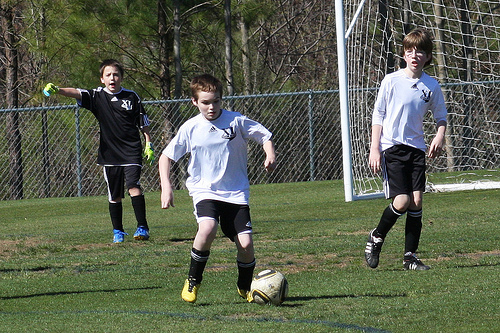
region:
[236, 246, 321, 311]
The soccer ball is on the ground.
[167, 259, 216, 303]
The boy is wearing yellow sneakers.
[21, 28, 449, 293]
The kids are playing soccer.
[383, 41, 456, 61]
the boy is wearing glasses.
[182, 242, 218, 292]
The boy has on black socks.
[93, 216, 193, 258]
The boy is wearing blue tennis shoes.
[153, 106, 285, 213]
The boy has on a white tee shirt.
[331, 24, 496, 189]
The white net is behind the boy.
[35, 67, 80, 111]
The boy is wearing gloves.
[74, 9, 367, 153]
Trees behind the fenced gate.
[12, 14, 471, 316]
Three young boys playing soccer.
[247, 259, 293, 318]
A white soccer ball.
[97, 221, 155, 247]
A pair of blue tennis shoes.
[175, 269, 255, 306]
A pair of yellow tennis shoes.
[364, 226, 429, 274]
A pair of black tennis shoes.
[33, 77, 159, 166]
Boy wearing yellow gloves.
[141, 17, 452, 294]
Two boys wearing same uniform.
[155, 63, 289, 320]
Boy getting ready to kick soccer ball.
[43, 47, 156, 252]
Boy wearing black uniform.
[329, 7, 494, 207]
Part of the white soccer goal.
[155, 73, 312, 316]
boy near soccer ball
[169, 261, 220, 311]
yellow shoe with black lace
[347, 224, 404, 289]
black and white shoe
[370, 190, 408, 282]
black sock with white trim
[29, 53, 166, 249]
boy yelling and pointing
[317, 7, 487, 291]
soccer goal behind player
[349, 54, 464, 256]
white shirt and black shorts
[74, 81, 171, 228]
black shirt and shorts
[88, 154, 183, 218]
white stripe on black shorts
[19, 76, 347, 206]
chain link fence behind soccer players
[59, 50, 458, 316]
Three boys playing soccer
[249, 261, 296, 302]
White soccer ball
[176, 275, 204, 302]
Cleat is yellow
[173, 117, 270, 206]
Shirt is white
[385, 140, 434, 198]
Pants are black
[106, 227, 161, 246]
These cleats are blue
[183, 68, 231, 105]
Hair is short and brown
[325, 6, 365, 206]
Goal post in background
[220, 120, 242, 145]
Black logo on shirt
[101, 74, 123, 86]
Boy's mouth is open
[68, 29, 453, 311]
three boys on soccer field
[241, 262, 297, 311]
soccer ball on grass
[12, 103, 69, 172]
pole on chain link fence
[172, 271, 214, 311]
yellow shoe on boy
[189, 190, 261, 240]
black shorts on boy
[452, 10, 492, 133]
strings on goal net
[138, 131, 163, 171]
yellow glove on hand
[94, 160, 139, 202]
shorts with white stripe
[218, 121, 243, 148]
emblem on shirt front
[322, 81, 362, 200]
pole of goal net